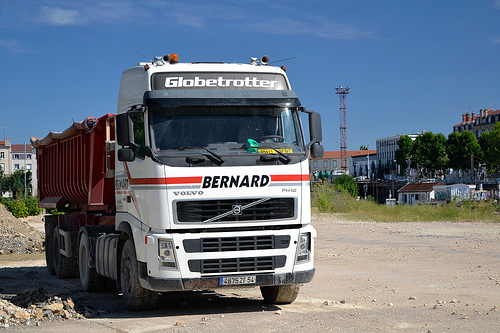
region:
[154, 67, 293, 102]
Model name on the truck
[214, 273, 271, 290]
License plate of the truck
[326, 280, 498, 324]
Rocks on the ground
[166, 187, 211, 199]
Make of the truck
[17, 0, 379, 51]
Small clouds in the sky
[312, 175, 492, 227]
Bushes growing on the ground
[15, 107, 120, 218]
Red bin of the dump truck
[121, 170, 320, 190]
Red stripe painted on the truck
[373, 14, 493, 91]
Pretty blue sky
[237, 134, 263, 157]
Green hat on the dashboard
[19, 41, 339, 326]
vehicle on the ground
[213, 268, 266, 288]
front licence plate on a vehicle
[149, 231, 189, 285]
front headlight on a vehicle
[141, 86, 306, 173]
front windshield on a vehicle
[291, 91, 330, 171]
side rear view mirror on a vehicle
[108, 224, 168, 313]
front wheel on a vehicle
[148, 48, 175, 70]
horn on top of a vehicle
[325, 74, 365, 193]
tower behind trees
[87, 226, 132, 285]
fuel tank on a vehicle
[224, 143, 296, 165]
windshield wiper on a vehicle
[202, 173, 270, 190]
word bernard in black lettering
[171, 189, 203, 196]
letters spelling volvo on a truck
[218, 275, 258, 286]
front license plate of a truck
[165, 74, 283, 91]
word globetrotter in white lettering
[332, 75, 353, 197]
tall metal tower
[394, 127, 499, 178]
row of healthy green trees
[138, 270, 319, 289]
silver bumper of a truck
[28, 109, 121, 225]
red cargo area of a truck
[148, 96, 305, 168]
windshield of a white truck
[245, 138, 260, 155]
green object inside cab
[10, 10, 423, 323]
Picture of a large truck.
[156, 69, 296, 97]
The word Globetrotter in white letters.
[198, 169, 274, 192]
The word BERNARD in black letters.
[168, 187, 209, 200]
The word VOLVO in silver letters.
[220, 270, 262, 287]
White license tag on bumper.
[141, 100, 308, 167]
Front windshield of truck.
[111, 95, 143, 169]
Passenger side mirror.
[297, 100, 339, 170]
Driver's side mirror.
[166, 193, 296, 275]
Grills on front of truck.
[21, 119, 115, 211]
The bed of trailer is red.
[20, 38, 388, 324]
a large work truck out in view.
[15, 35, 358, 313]
a heavy duty work truck out in view.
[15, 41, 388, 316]
a huge work truck out in view.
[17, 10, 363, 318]
powerful work truck out in view.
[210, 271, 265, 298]
license plate on front of work truck.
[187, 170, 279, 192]
front of truck reading "bernard".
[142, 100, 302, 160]
front windshield of work truck.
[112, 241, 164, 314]
right front wheel area of truck.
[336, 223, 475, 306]
patch of ground area.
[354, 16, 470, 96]
patch of blue sky.